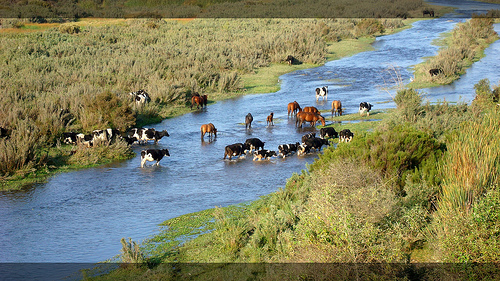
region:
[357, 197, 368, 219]
edge of a bush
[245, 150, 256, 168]
body of a cow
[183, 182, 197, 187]
part of a river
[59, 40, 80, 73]
part of a forest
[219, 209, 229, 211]
edge of a shore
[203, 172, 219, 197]
part of a river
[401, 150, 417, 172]
part of a forest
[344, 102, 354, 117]
body of a black cow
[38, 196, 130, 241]
Water is blue color.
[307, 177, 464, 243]
Grass is green and brown color.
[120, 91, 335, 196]
Animals are in water.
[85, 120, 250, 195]
Cows are black and white color.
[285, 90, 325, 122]
Horse are brown color.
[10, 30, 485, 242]
Day time picture.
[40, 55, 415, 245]
Tall grass are seen on both sides of water.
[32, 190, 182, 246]
Water is calm and clear.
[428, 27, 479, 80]
Grass are between the water.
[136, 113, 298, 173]
Animals are walking in the water.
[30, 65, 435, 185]
Cows and horses in a river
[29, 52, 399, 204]
Cows and horse crossing a river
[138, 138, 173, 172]
A cow in a river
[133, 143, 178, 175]
A cow standing in water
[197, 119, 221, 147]
A horse in the water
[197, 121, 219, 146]
A horse standing in the river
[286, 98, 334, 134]
Horses together in the water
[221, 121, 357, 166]
Several cows crossing the river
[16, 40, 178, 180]
Cows on the bank of the river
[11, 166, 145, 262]
A river flowing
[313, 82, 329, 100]
Black or white cow in water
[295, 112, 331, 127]
Brown horse drinking water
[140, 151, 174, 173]
Black and white cow in water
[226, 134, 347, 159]
Cows walking through water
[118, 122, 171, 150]
Cows crossing river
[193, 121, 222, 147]
Horse standing in water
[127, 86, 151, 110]
Cow standing in the grass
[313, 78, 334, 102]
Cow moving forward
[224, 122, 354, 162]
Group of cows crossing river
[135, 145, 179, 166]
Cow looking forward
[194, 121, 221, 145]
animal standing in the water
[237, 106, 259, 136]
animal standing in the water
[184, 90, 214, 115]
animal standing in the water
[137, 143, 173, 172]
animal standing in the water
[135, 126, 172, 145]
animal standing in the water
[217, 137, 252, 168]
animal standing in the water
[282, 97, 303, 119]
animal standing in the water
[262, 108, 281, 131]
animal standing in the water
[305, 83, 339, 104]
animal standing in the water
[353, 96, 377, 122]
animal standing in the water